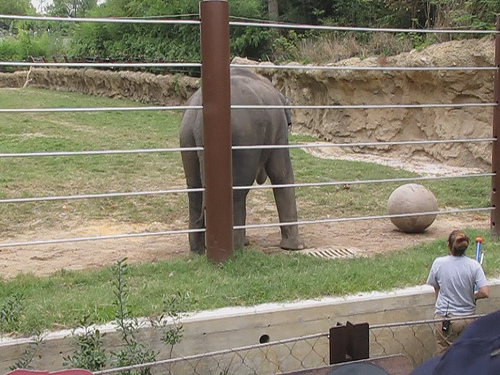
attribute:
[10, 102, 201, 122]
pole — silver, metal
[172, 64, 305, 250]
elephant — inside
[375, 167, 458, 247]
ball — white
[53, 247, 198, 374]
plant — tall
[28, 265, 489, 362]
wall — cement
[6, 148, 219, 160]
fence — metal, silver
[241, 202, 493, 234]
fence — silver, metal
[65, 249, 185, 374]
plant — tall, green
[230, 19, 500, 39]
wires — metal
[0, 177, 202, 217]
pole — silver, metal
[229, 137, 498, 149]
pole — metal, silver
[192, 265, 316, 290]
grass — natural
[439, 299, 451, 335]
radio — two way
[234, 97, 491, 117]
pole — silver, metal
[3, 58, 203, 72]
pole — metal, silver